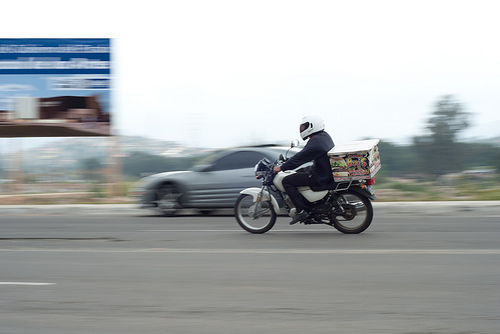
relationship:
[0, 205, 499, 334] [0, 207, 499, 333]
street for traveling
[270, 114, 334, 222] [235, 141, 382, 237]
person on motorcycle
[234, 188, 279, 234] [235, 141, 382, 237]
wheel on motorcycle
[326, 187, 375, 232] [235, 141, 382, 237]
wheel on motorcycle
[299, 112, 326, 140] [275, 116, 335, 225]
helmet on biker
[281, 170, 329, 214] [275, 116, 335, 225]
pants on biker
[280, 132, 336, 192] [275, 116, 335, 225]
jacket on biker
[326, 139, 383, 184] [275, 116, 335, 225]
basket on biker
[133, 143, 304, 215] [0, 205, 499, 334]
vehicle on street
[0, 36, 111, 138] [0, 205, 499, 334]
billboard on street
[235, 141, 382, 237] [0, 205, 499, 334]
motorcycle on street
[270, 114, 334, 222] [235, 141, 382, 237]
person riding motorcycle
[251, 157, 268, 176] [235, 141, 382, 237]
headlight on motorcycle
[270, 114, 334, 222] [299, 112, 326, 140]
person wearing helmet